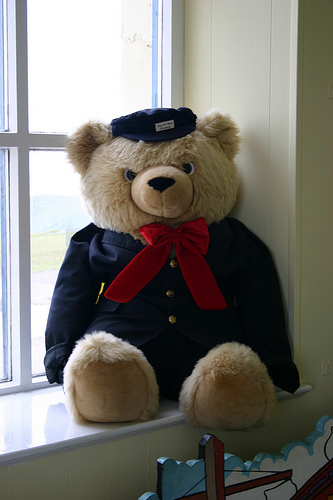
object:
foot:
[178, 341, 275, 432]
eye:
[121, 165, 138, 185]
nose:
[147, 176, 177, 193]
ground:
[221, 58, 263, 101]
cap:
[109, 105, 200, 142]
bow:
[105, 217, 228, 309]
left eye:
[178, 161, 195, 176]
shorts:
[92, 319, 229, 400]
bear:
[43, 105, 300, 430]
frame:
[0, 0, 172, 388]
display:
[139, 412, 331, 498]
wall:
[171, 0, 332, 384]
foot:
[63, 332, 158, 428]